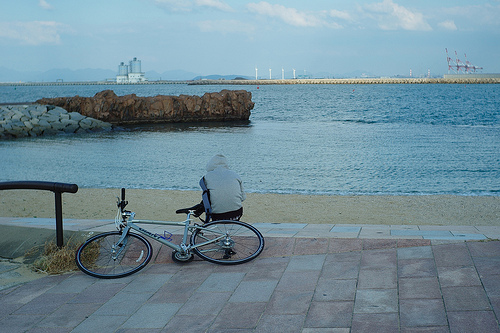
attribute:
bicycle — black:
[88, 186, 204, 286]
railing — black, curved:
[2, 175, 80, 195]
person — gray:
[200, 145, 248, 220]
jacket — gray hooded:
[211, 167, 233, 182]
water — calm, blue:
[62, 89, 256, 128]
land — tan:
[300, 209, 396, 240]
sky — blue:
[241, 20, 301, 48]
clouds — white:
[299, 12, 367, 28]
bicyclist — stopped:
[177, 144, 250, 234]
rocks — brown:
[101, 92, 136, 114]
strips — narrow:
[296, 80, 369, 87]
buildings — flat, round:
[114, 56, 147, 67]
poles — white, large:
[252, 64, 303, 80]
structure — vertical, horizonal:
[116, 48, 142, 84]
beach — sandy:
[268, 184, 406, 227]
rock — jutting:
[198, 89, 251, 115]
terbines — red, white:
[437, 49, 458, 70]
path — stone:
[305, 228, 370, 237]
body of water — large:
[296, 109, 382, 152]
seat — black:
[174, 203, 203, 217]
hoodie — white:
[206, 153, 226, 169]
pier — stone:
[191, 78, 270, 86]